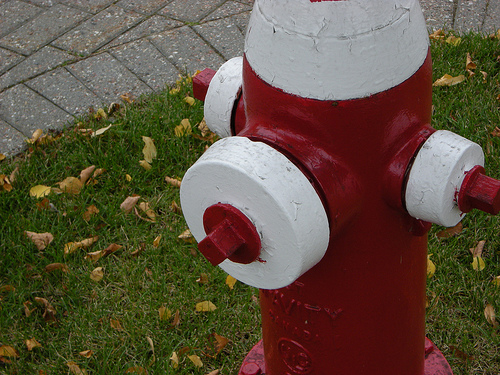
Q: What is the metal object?
A: Fire hydrant.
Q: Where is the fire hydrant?
A: On the grass.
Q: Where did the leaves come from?
A: Trees.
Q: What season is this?
A: Fall.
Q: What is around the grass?
A: Sidewalk.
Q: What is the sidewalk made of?
A: Bricks.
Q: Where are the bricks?
A: On the sidewalk.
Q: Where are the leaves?
A: On the grass.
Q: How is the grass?
A: Tall.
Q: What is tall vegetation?
A: Grass.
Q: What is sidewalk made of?
A: Brick.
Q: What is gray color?
A: Sidewalk.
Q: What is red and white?
A: Hydrant.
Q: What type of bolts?
A: Hex.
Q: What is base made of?
A: Metal.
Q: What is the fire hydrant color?
A: Red and white.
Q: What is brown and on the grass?
A: Leaves.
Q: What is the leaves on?
A: Grass.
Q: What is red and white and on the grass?
A: Fire hydrant.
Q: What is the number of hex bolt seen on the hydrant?
A: Three.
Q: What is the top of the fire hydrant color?
A: White.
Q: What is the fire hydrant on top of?
A: Grass.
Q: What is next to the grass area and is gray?
A: Sidewalk.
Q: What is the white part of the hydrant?
A: Valve.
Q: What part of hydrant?
A: Valve.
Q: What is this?
A: A fire hydrant.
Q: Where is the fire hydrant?
A: In the grass.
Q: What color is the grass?
A: Green.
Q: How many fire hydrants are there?
A: One.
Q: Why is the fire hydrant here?
A: To aid in putting out fires.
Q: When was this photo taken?
A: During the daytime.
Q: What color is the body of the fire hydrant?
A: Red.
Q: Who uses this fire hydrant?
A: Firemen.